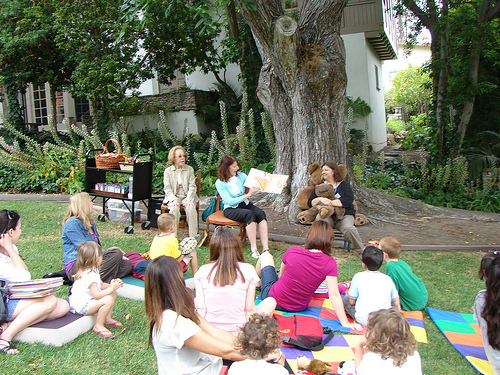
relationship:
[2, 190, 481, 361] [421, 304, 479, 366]
people sitting blankets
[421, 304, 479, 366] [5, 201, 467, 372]
blankets on ground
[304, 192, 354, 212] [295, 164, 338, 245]
arms wrapped bear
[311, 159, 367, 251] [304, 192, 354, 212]
lady with arms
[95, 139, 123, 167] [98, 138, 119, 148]
basket with handle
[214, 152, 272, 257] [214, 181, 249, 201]
lady with sweater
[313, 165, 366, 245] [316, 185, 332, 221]
lady with bear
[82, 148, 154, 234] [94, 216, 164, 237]
cart with wheels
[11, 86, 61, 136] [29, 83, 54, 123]
window with panes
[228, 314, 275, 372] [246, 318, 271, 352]
child with hair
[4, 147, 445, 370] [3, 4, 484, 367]
people are outside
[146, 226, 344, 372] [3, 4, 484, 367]
adults are outside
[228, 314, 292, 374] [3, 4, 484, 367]
child are outside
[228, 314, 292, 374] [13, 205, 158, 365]
child on ground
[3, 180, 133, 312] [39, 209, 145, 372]
adults on ground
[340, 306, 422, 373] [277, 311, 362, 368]
children on mats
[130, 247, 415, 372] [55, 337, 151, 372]
children on grass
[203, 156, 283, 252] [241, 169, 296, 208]
lady with book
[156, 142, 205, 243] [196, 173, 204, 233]
woman on chair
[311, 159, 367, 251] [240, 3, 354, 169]
lady under tree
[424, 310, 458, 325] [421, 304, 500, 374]
square on blankets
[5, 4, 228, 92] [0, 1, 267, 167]
leaves on trees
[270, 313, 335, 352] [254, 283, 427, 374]
backpack middle of blanket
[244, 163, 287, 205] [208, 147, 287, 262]
book read by lady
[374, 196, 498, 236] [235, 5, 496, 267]
dirt in front of tree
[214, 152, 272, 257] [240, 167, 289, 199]
lady reading aloud story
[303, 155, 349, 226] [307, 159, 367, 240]
bear behind woman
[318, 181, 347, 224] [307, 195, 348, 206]
bear in arm's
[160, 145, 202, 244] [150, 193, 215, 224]
woman sitting on chair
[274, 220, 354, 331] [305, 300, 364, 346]
girl sitting on mat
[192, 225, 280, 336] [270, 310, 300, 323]
adults sitting on mat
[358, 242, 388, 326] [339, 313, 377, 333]
boy sitting on mat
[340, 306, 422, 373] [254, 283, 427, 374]
children sitting on blanket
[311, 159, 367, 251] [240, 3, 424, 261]
lady sitting next to tree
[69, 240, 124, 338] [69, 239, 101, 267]
child with hair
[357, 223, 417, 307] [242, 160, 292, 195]
boys listening to story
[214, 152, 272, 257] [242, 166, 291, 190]
lady reading story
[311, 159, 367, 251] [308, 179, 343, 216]
lady holding bear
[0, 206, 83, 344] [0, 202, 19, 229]
woman with hair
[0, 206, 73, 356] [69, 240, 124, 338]
woman and child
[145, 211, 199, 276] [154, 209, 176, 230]
boy with hair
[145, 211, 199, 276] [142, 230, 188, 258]
boy with shirt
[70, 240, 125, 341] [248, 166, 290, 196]
child listening to story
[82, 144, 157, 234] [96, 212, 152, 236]
cart on wheels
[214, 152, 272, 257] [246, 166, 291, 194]
lady holding a book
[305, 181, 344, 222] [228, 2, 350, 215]
bear resting against a tree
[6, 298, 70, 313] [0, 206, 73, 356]
lap of a woman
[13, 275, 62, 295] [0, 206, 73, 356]
books stacked on a woman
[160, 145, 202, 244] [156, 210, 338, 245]
woman sitting on chairs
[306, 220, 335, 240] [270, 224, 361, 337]
hair of a woman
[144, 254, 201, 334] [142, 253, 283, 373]
hair of a people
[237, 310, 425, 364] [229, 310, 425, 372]
hair on children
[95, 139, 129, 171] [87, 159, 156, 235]
basket on a cart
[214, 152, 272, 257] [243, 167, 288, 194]
lady reading a story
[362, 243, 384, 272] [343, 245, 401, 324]
hair of a boy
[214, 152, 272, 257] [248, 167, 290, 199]
lady holding a book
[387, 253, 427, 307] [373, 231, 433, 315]
shirt of a boy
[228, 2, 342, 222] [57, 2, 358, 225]
trunk of a tree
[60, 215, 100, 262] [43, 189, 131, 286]
shirt of a adults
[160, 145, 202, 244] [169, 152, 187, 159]
woman with sunglasses